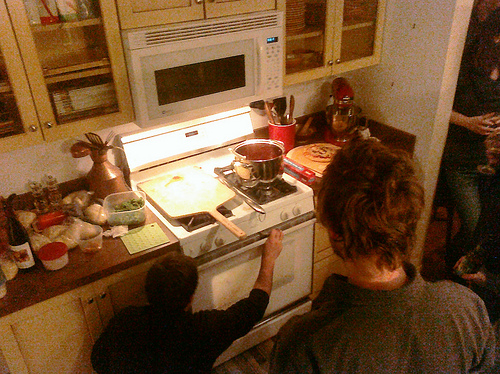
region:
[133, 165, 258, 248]
A wooden pizza peel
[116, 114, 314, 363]
A white oven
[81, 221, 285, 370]
A person bent down by an oven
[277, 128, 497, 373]
A person standing with a stove in front of it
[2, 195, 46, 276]
A dark tall bottle with a white label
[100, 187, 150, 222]
A clear plastic container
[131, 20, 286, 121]
A white microwave above the oven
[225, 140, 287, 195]
A silver pot on top of the stove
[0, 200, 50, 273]
A bottle of wine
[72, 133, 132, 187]
Kitchen utensils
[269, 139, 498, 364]
this is a person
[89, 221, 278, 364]
this is a person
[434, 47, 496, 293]
this is a person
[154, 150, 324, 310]
this is a gas cooker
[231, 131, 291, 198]
this is a cooking pot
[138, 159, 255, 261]
this is a pan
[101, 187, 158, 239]
this is a dish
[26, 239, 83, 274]
this is a dish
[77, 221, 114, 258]
this is a dish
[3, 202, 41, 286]
this is a bottle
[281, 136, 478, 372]
person standing over oven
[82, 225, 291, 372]
person adjusting oven settings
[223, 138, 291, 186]
pot on the oven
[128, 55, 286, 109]
microwave above the stove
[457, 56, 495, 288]
people at the gathering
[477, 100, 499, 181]
glass in person's hand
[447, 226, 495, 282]
beverage in person's hand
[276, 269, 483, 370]
shirt on the man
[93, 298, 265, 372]
shirt on the man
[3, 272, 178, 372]
cabinets near the stove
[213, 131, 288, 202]
the pot on the stove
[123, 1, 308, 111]
the microwave above the stove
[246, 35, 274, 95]
the handle on microwave door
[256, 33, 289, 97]
the panel of the microwave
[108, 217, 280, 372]
the person beside the oven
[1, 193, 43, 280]
the bottle on the counter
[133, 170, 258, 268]
the pizza paddle on the stove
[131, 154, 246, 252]
the pizza paddle is wooden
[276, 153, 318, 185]
the box of foil beside the pot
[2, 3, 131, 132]
the cupboards with glass doors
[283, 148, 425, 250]
head of a person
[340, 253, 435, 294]
neck of a person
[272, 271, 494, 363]
shoulder of a person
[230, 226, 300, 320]
arm of a person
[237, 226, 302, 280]
hand of a person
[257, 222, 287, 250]
fingers of a person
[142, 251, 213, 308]
head of a person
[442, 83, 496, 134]
arm of a person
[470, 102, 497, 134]
hand of a person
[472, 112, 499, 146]
fingers of a person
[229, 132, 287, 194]
pot with something red in it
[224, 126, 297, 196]
pot with something red in it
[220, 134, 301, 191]
pot with something red in it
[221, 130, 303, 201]
pot with something red in it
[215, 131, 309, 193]
pot with something red in it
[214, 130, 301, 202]
pot with something red in it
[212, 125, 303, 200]
pot with something red in it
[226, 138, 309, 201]
silver pot on stove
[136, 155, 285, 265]
cutting board on stove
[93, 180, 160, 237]
greens chopped in bowl